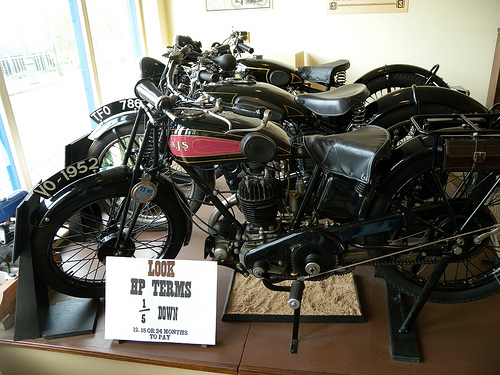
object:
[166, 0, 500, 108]
wall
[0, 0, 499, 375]
picture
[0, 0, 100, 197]
window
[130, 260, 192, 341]
sign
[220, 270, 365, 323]
tray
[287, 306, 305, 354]
kickstand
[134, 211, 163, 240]
spoke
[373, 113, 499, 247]
rack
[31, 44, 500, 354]
bike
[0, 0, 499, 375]
shop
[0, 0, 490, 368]
display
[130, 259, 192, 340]
ad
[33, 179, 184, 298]
tire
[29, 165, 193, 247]
cover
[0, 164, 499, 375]
platform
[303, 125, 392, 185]
seats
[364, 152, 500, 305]
wheel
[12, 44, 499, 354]
surface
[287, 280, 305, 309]
pedal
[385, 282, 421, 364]
board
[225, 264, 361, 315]
sand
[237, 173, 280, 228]
engine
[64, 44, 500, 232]
row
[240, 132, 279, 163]
tank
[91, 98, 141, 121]
tfo 786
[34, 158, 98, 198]
vo 1952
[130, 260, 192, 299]
look hp terms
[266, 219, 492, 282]
chain